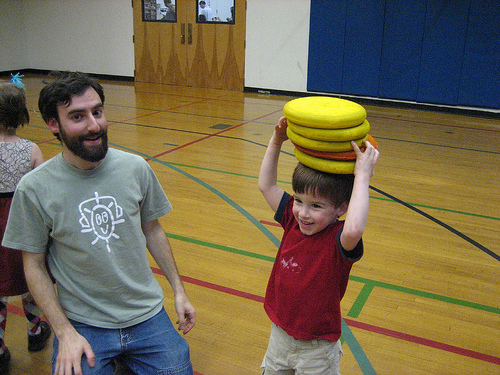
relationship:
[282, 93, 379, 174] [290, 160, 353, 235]
frisbees on top of head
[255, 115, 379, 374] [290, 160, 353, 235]
boy has head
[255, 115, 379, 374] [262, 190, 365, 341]
boy wearing shirt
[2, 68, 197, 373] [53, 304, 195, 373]
man wearing jeans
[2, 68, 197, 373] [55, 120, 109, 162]
man with beard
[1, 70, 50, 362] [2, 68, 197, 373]
girl behind man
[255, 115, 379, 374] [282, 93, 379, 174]
boy balancing frisbees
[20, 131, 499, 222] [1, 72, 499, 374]
line on floor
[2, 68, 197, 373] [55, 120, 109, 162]
man has beard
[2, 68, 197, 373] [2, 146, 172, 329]
man wearing shirt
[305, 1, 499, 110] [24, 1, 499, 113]
padding attached to wall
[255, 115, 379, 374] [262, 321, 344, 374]
boy wearing pants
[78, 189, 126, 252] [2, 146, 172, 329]
image printed on shirt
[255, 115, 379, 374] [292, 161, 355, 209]
boy has hair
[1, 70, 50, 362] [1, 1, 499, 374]
girl inside of gymnasium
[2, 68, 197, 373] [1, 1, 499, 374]
man inside of gymnasium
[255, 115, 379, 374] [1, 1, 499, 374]
boy inside of gymnasium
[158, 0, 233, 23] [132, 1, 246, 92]
people outside of doors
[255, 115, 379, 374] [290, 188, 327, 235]
boy has face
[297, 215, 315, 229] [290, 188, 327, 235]
smile on face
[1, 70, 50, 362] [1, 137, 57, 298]
girl wearing dress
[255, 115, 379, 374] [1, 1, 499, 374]
boy playing in gymnasium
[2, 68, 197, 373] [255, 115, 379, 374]
man next to boy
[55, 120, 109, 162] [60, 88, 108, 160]
beard grown on face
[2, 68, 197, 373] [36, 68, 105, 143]
man has hair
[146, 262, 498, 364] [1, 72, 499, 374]
line on floor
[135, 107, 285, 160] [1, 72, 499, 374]
line on floor